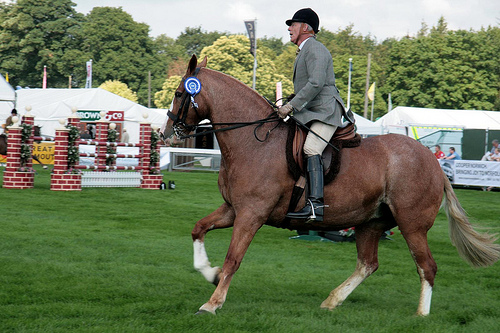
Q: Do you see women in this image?
A: No, there are no women.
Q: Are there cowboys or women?
A: No, there are no women or cowboys.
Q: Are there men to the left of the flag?
A: Yes, there is a man to the left of the flag.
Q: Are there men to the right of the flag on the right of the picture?
A: No, the man is to the left of the flag.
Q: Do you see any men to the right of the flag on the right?
A: No, the man is to the left of the flag.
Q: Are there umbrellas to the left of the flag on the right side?
A: No, there is a man to the left of the flag.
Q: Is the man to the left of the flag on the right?
A: Yes, the man is to the left of the flag.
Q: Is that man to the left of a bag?
A: No, the man is to the left of the flag.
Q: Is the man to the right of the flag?
A: No, the man is to the left of the flag.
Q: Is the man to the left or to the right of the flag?
A: The man is to the left of the flag.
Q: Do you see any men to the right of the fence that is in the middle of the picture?
A: Yes, there is a man to the right of the fence.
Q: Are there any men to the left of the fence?
A: No, the man is to the right of the fence.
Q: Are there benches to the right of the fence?
A: No, there is a man to the right of the fence.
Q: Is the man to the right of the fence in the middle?
A: Yes, the man is to the right of the fence.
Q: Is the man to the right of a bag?
A: No, the man is to the right of the fence.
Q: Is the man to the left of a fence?
A: No, the man is to the right of a fence.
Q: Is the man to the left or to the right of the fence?
A: The man is to the right of the fence.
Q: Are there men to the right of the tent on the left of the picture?
A: Yes, there is a man to the right of the tent.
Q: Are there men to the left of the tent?
A: No, the man is to the right of the tent.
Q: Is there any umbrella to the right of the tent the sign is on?
A: No, there is a man to the right of the tent.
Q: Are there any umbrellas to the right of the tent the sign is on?
A: No, there is a man to the right of the tent.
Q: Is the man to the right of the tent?
A: Yes, the man is to the right of the tent.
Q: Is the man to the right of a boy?
A: No, the man is to the right of the tent.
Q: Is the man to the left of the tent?
A: No, the man is to the right of the tent.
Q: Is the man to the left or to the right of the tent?
A: The man is to the right of the tent.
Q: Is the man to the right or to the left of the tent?
A: The man is to the right of the tent.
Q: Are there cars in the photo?
A: No, there are no cars.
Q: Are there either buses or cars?
A: No, there are no cars or buses.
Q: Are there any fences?
A: Yes, there is a fence.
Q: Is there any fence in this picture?
A: Yes, there is a fence.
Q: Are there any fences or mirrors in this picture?
A: Yes, there is a fence.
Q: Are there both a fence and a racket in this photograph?
A: No, there is a fence but no rackets.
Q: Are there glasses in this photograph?
A: No, there are no glasses.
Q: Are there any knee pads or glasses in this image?
A: No, there are no glasses or knee pads.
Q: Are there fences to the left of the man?
A: Yes, there is a fence to the left of the man.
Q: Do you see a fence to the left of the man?
A: Yes, there is a fence to the left of the man.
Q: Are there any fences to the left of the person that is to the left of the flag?
A: Yes, there is a fence to the left of the man.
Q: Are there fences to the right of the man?
A: No, the fence is to the left of the man.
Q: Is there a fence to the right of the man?
A: No, the fence is to the left of the man.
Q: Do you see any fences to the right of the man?
A: No, the fence is to the left of the man.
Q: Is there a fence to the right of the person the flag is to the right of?
A: No, the fence is to the left of the man.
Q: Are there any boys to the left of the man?
A: No, there is a fence to the left of the man.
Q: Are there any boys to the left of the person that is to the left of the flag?
A: No, there is a fence to the left of the man.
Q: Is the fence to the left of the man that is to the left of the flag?
A: Yes, the fence is to the left of the man.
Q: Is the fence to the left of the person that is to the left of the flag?
A: Yes, the fence is to the left of the man.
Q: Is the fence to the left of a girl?
A: No, the fence is to the left of the man.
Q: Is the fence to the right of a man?
A: No, the fence is to the left of a man.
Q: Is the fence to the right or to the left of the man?
A: The fence is to the left of the man.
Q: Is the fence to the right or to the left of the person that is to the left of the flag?
A: The fence is to the left of the man.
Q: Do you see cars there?
A: No, there are no cars.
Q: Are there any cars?
A: No, there are no cars.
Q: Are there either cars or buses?
A: No, there are no cars or buses.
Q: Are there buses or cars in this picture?
A: No, there are no cars or buses.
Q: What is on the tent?
A: The sign is on the tent.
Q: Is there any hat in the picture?
A: Yes, there is a hat.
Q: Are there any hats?
A: Yes, there is a hat.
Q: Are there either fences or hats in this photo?
A: Yes, there is a hat.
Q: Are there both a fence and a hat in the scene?
A: Yes, there are both a hat and a fence.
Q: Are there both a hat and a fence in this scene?
A: Yes, there are both a hat and a fence.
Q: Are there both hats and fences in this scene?
A: Yes, there are both a hat and a fence.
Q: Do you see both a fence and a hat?
A: Yes, there are both a hat and a fence.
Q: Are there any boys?
A: No, there are no boys.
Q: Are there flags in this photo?
A: Yes, there is a flag.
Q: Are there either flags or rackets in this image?
A: Yes, there is a flag.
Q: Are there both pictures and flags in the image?
A: No, there is a flag but no pictures.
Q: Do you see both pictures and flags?
A: No, there is a flag but no pictures.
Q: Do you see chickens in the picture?
A: No, there are no chickens.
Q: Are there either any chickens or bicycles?
A: No, there are no chickens or bicycles.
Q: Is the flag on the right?
A: Yes, the flag is on the right of the image.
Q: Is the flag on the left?
A: No, the flag is on the right of the image.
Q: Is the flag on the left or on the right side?
A: The flag is on the right of the image.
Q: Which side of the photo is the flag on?
A: The flag is on the right of the image.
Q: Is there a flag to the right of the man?
A: Yes, there is a flag to the right of the man.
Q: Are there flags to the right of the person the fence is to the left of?
A: Yes, there is a flag to the right of the man.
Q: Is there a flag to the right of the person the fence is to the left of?
A: Yes, there is a flag to the right of the man.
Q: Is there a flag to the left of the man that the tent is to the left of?
A: No, the flag is to the right of the man.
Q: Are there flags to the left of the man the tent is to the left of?
A: No, the flag is to the right of the man.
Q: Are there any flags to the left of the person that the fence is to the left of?
A: No, the flag is to the right of the man.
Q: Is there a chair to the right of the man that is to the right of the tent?
A: No, there is a flag to the right of the man.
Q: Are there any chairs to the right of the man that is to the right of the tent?
A: No, there is a flag to the right of the man.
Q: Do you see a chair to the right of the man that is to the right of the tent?
A: No, there is a flag to the right of the man.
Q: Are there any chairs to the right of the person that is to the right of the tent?
A: No, there is a flag to the right of the man.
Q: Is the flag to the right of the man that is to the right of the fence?
A: Yes, the flag is to the right of the man.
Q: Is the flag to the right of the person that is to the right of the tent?
A: Yes, the flag is to the right of the man.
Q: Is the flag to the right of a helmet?
A: No, the flag is to the right of the man.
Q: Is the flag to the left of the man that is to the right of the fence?
A: No, the flag is to the right of the man.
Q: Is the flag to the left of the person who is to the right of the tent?
A: No, the flag is to the right of the man.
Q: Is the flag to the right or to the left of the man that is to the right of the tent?
A: The flag is to the right of the man.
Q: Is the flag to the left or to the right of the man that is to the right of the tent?
A: The flag is to the right of the man.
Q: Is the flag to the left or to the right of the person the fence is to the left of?
A: The flag is to the right of the man.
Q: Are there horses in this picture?
A: Yes, there is a horse.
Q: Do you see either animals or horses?
A: Yes, there is a horse.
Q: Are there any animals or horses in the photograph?
A: Yes, there is a horse.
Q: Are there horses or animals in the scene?
A: Yes, there is a horse.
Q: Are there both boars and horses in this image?
A: No, there is a horse but no boars.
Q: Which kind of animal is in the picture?
A: The animal is a horse.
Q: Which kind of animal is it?
A: The animal is a horse.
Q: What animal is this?
A: This is a horse.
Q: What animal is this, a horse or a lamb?
A: This is a horse.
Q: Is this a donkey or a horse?
A: This is a horse.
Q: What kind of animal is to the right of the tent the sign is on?
A: The animal is a horse.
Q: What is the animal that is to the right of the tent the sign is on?
A: The animal is a horse.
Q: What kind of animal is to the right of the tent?
A: The animal is a horse.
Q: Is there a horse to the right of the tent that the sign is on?
A: Yes, there is a horse to the right of the tent.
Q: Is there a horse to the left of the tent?
A: No, the horse is to the right of the tent.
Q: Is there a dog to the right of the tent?
A: No, there is a horse to the right of the tent.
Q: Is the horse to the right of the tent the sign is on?
A: Yes, the horse is to the right of the tent.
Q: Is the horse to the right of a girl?
A: No, the horse is to the right of the tent.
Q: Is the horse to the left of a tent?
A: No, the horse is to the right of a tent.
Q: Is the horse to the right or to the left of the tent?
A: The horse is to the right of the tent.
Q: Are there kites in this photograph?
A: No, there are no kites.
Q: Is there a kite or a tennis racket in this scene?
A: No, there are no kites or rackets.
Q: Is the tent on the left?
A: Yes, the tent is on the left of the image.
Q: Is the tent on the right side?
A: No, the tent is on the left of the image.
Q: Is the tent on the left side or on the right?
A: The tent is on the left of the image.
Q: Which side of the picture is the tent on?
A: The tent is on the left of the image.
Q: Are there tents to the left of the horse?
A: Yes, there is a tent to the left of the horse.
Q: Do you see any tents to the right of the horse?
A: No, the tent is to the left of the horse.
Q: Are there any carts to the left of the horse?
A: No, there is a tent to the left of the horse.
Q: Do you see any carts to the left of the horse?
A: No, there is a tent to the left of the horse.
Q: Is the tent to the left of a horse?
A: Yes, the tent is to the left of a horse.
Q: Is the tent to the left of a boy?
A: No, the tent is to the left of a horse.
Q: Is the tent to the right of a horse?
A: No, the tent is to the left of a horse.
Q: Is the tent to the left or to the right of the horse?
A: The tent is to the left of the horse.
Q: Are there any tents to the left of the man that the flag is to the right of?
A: Yes, there is a tent to the left of the man.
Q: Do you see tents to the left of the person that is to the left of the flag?
A: Yes, there is a tent to the left of the man.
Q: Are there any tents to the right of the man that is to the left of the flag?
A: No, the tent is to the left of the man.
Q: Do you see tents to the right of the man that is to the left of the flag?
A: No, the tent is to the left of the man.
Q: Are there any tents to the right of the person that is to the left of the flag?
A: No, the tent is to the left of the man.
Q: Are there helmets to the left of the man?
A: No, there is a tent to the left of the man.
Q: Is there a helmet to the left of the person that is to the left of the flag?
A: No, there is a tent to the left of the man.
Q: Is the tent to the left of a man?
A: Yes, the tent is to the left of a man.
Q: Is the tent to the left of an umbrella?
A: No, the tent is to the left of a man.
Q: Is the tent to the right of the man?
A: No, the tent is to the left of the man.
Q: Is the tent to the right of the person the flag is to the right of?
A: No, the tent is to the left of the man.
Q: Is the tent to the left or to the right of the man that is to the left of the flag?
A: The tent is to the left of the man.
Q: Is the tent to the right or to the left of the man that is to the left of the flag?
A: The tent is to the left of the man.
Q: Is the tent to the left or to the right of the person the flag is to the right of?
A: The tent is to the left of the man.